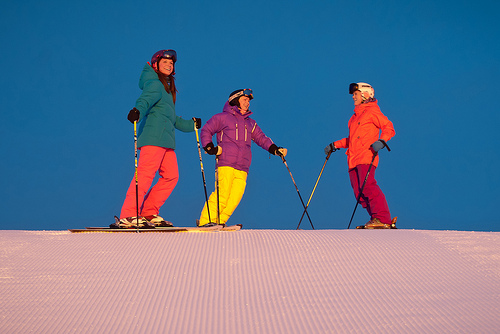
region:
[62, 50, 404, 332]
three women ready to ski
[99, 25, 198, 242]
woman in green and orange preparing to ski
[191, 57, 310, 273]
woman in yellow and purple preparing to ski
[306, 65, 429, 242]
woman in orange and purple preparing to ski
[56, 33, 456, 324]
woman at the top of a ski hill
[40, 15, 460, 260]
bright blue sky behind three skiers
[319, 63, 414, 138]
girl with helmet and orange coat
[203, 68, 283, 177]
girl with black helmet and purple coat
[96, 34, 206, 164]
woman in a green coat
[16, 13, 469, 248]
three women enjoying themselves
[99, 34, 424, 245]
women preparing to ski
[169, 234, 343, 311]
lined tracks in snow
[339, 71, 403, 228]
a woman wearing an orange jacket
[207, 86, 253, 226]
a woman wearing a purple parka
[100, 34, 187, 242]
a teenager dressed in a teal jacket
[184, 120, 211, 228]
a multicolored ski pole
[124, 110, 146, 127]
a hand covered in a black glove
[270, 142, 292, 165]
a hand grasping a ski pole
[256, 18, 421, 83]
a gorgeous cerulean blue sky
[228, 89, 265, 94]
snow goggles on top of a head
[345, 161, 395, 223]
Dark purple pants on the woman.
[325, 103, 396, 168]
A bright orange coat on the woman.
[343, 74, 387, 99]
A white helmet with goggles.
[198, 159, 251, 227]
Bright yellow pants on the woman.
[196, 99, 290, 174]
A purple winter coat on the woman.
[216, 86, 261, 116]
A black helmet with goggles.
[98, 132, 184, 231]
A pair of peach colored pants on the woman.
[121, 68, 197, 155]
A green winter coat on the woman.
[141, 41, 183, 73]
A purple helmet with goggles.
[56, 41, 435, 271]
Three women wearing ski gear.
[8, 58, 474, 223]
the sky is blue in color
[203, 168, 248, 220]
the pants are yellow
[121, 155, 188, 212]
the pants are red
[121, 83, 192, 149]
the jacket is blue in color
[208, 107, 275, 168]
the jacket is purple in color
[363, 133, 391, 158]
the gloves are grey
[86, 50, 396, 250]
there are three people skiing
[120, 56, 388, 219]
the three people have helmets on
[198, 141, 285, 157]
the gloves are black in color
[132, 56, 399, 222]
the skiis are six in total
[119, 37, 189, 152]
a woman wearing a green jacket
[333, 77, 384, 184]
a woman wearing a orange jacket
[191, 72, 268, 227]
a woman wearing yellow pants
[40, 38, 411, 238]
three woman with ski poles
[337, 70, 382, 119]
a woman wearing a white helmet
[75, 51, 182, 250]
a woman wearing skis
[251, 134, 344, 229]
two ski poles crossed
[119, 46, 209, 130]
a woman wearing black gloves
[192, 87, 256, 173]
a woman with her hand on her hip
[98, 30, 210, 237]
a woman holding ski poles